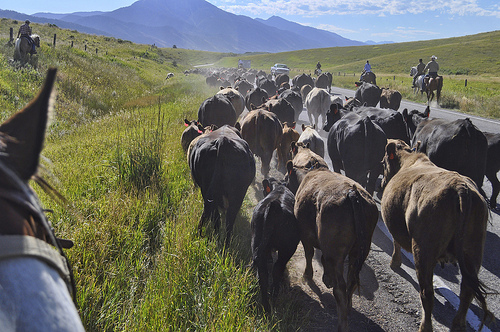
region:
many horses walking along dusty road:
[171, 65, 491, 325]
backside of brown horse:
[427, 178, 491, 246]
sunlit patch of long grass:
[89, 163, 192, 325]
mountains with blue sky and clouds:
[46, 3, 408, 44]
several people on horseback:
[304, 55, 449, 100]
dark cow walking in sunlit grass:
[186, 125, 258, 252]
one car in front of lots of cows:
[248, 60, 313, 118]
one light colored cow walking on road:
[301, 83, 334, 128]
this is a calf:
[237, 166, 307, 321]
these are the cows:
[276, 139, 493, 326]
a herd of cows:
[185, 65, 495, 330]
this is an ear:
[8, 42, 70, 201]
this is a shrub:
[95, 120, 182, 194]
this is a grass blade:
[91, 135, 101, 157]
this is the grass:
[88, 121, 170, 246]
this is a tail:
[451, 179, 493, 321]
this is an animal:
[238, 104, 410, 330]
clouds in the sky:
[247, 3, 481, 29]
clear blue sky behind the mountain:
[18, 2, 123, 18]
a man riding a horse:
[15, 12, 40, 67]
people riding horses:
[298, 55, 464, 96]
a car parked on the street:
[267, 57, 288, 69]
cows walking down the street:
[187, 61, 494, 272]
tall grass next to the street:
[102, 97, 204, 288]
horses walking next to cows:
[10, 17, 497, 242]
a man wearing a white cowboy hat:
[424, 53, 439, 82]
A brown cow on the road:
[377, 136, 492, 330]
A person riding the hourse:
[10, 18, 45, 66]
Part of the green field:
[456, 48, 471, 68]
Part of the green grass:
[69, 136, 90, 161]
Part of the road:
[436, 109, 447, 116]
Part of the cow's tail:
[456, 250, 488, 308]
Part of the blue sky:
[359, 17, 376, 23]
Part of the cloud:
[306, 1, 320, 7]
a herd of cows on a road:
[173, 59, 499, 328]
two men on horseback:
[408, 53, 446, 109]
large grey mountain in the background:
[5, 1, 385, 56]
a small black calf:
[247, 168, 300, 318]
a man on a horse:
[8, 15, 43, 71]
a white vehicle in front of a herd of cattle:
[268, 57, 293, 79]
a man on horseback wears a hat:
[420, 54, 450, 103]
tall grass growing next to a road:
[105, 96, 172, 199]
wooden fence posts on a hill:
[1, 23, 122, 63]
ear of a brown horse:
[0, 52, 65, 193]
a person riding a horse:
[10, 18, 44, 65]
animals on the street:
[133, 47, 488, 258]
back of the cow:
[308, 175, 388, 262]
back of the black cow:
[173, 135, 255, 215]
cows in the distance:
[169, 53, 321, 117]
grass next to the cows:
[83, 123, 178, 230]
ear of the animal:
[3, 53, 84, 173]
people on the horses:
[330, 43, 471, 105]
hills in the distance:
[222, 7, 339, 54]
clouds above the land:
[361, 1, 452, 33]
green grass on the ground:
[441, 28, 483, 71]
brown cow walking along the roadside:
[378, 137, 488, 330]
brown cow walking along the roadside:
[288, 147, 383, 324]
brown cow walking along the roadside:
[238, 106, 283, 186]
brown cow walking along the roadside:
[277, 124, 302, 160]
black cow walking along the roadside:
[245, 173, 295, 318]